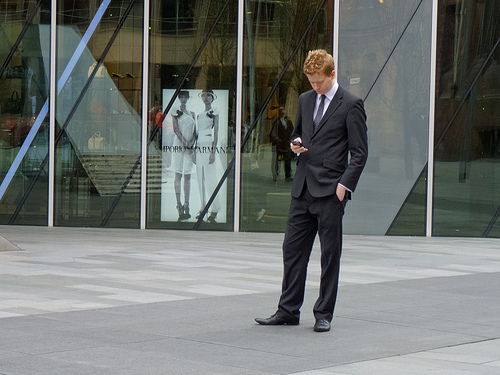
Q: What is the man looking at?
A: Cell phone.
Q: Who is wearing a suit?
A: The man.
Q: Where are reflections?
A: On the windows.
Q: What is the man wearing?
A: A suit.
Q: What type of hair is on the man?
A: Red.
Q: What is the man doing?
A: Checking his phone.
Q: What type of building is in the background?
A: A shop.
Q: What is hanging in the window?
A: An advertisement.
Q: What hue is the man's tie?
A: Blue.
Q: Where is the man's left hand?
A: A pocket.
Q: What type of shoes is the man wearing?
A: Dress.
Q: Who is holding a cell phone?
A: The man.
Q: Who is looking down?
A: The man.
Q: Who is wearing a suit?
A: The man.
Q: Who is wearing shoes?
A: The man.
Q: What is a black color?
A: Shoes.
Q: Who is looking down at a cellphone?
A: The man.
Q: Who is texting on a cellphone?
A: A man.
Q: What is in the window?
A: A fashion poster.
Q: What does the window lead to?
A: A retail location.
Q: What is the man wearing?
A: Black blazer jacket.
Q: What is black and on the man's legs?
A: Pants.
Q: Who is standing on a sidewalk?
A: A man.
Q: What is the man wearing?
A: Black suit.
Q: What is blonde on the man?
A: Hair.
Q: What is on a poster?
A: Two women.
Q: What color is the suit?
A: Black.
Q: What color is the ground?
A: Grey.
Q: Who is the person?
A: A man.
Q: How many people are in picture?
A: One.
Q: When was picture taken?
A: Daytime.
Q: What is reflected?
A: Sun.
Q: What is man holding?
A: Phone.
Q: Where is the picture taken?
A: Outside a commercial building.